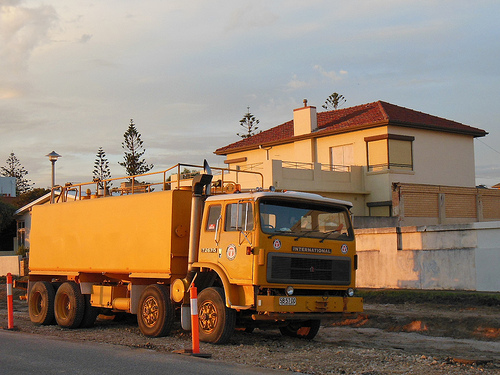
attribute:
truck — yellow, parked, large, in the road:
[13, 176, 371, 348]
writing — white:
[286, 246, 335, 254]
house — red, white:
[215, 97, 490, 226]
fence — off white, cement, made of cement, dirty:
[348, 183, 500, 295]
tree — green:
[4, 152, 35, 204]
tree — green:
[89, 145, 115, 196]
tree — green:
[116, 121, 157, 191]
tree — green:
[240, 108, 269, 137]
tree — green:
[320, 97, 353, 110]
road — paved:
[0, 327, 216, 364]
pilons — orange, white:
[0, 275, 211, 353]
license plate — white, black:
[275, 295, 302, 305]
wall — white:
[350, 227, 496, 296]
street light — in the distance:
[45, 150, 65, 204]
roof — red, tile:
[214, 96, 491, 158]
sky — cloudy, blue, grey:
[8, 6, 498, 190]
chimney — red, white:
[290, 97, 320, 139]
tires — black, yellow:
[26, 275, 241, 348]